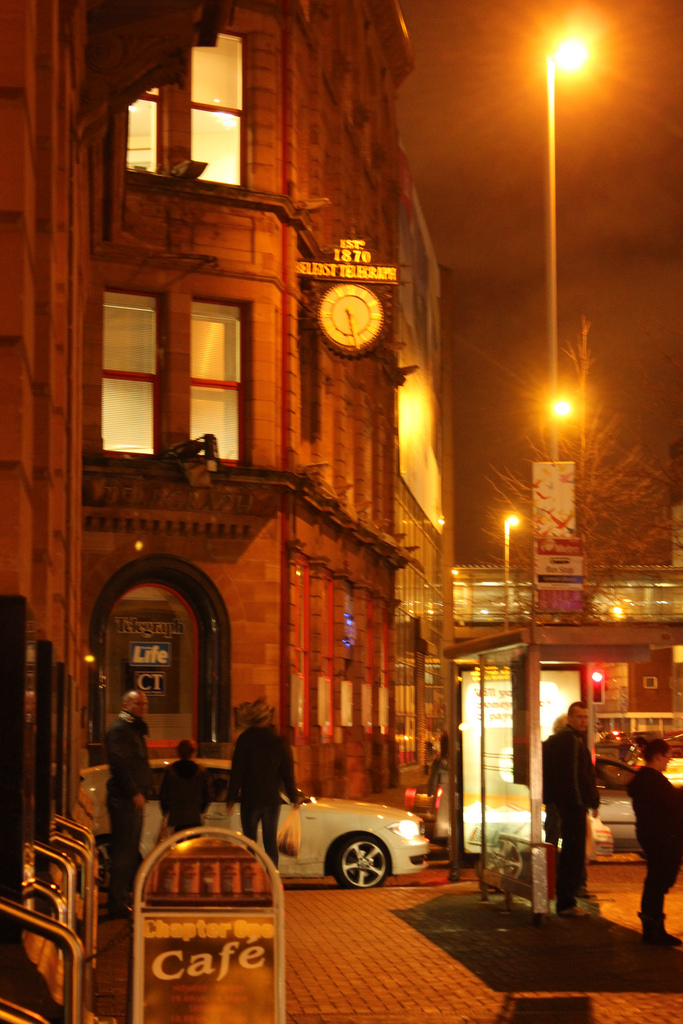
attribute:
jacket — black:
[228, 728, 294, 793]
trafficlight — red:
[589, 670, 608, 687]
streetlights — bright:
[541, 391, 578, 425]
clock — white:
[314, 282, 395, 351]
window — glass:
[187, 25, 252, 108]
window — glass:
[124, 98, 163, 172]